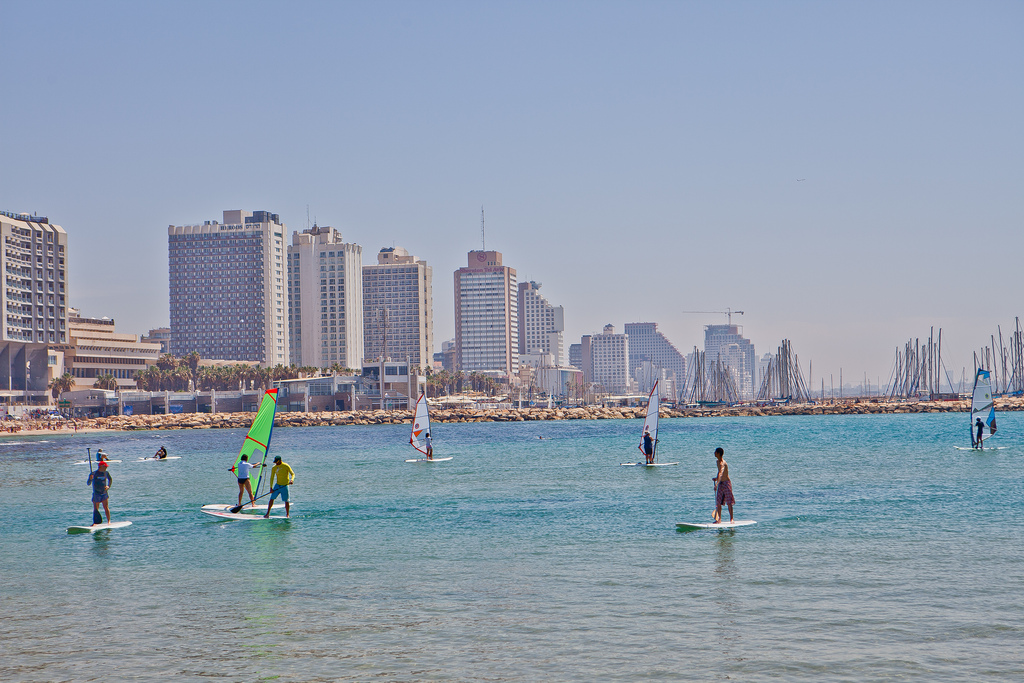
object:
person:
[238, 454, 262, 507]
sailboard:
[227, 387, 281, 500]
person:
[712, 447, 736, 523]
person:
[644, 432, 653, 464]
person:
[975, 418, 984, 450]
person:
[425, 433, 431, 460]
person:
[87, 461, 112, 526]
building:
[167, 210, 290, 371]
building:
[287, 205, 363, 370]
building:
[361, 247, 432, 376]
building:
[454, 205, 519, 388]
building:
[517, 275, 564, 375]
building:
[581, 323, 628, 396]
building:
[624, 322, 687, 400]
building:
[704, 324, 754, 401]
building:
[47, 307, 164, 406]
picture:
[0, 0, 1024, 683]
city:
[0, 210, 1024, 421]